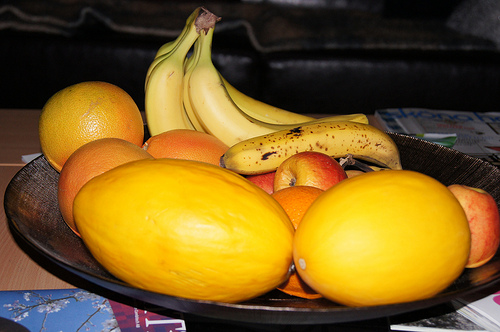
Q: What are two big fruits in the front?
A: Melons.